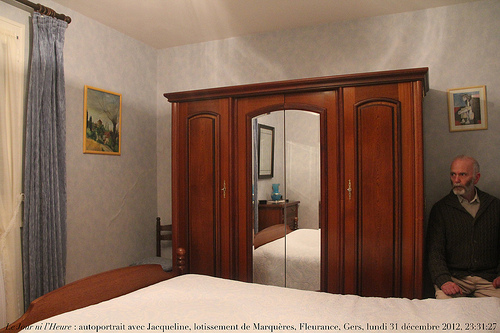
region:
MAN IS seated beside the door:
[433, 141, 493, 278]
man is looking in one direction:
[432, 134, 495, 268]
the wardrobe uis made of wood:
[334, 89, 417, 261]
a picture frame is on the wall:
[94, 50, 158, 189]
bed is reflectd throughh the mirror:
[268, 227, 320, 297]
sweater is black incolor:
[444, 199, 497, 251]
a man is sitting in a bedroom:
[353, 40, 498, 321]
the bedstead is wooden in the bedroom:
[19, 256, 499, 331]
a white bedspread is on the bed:
[27, 266, 498, 331]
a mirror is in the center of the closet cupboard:
[159, 64, 435, 304]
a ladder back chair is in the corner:
[123, 210, 179, 278]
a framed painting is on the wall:
[1, 0, 135, 327]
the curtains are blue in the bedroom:
[19, 3, 74, 308]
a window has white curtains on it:
[3, 12, 33, 332]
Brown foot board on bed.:
[0, 259, 199, 331]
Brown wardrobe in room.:
[163, 65, 428, 307]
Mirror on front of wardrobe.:
[243, 106, 326, 293]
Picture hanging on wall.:
[73, 82, 133, 159]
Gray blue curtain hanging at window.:
[14, 12, 73, 297]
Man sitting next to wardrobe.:
[413, 150, 499, 296]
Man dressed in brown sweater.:
[426, 182, 499, 286]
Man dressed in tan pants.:
[434, 276, 498, 298]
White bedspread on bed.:
[141, 268, 494, 327]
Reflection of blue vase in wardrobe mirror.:
[263, 179, 288, 204]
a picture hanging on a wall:
[77, 79, 129, 174]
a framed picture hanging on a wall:
[440, 70, 490, 136]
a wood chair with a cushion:
[135, 201, 165, 266]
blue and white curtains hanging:
[0, 52, 66, 233]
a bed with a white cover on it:
[27, 282, 391, 329]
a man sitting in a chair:
[425, 142, 489, 302]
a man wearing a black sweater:
[452, 187, 487, 254]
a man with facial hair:
[442, 176, 480, 203]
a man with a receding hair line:
[444, 148, 481, 174]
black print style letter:
[76, 322, 85, 332]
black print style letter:
[85, 320, 92, 330]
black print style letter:
[126, 321, 133, 329]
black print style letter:
[143, 320, 151, 330]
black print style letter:
[159, 321, 166, 330]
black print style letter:
[238, 320, 247, 329]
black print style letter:
[252, 318, 259, 328]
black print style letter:
[298, 319, 308, 331]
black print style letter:
[343, 318, 352, 330]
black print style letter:
[399, 318, 407, 330]